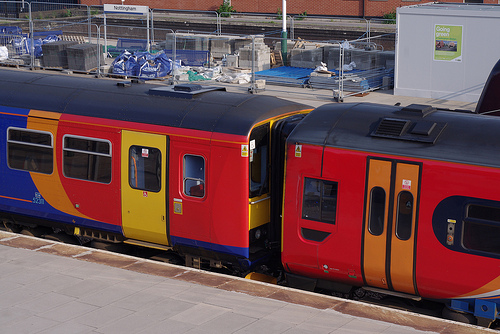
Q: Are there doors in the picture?
A: Yes, there is a door.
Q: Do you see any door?
A: Yes, there is a door.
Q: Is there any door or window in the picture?
A: Yes, there is a door.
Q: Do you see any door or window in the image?
A: Yes, there is a door.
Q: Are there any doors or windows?
A: Yes, there is a door.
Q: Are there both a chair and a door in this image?
A: No, there is a door but no chairs.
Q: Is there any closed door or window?
A: Yes, there is a closed door.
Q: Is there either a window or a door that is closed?
A: Yes, the door is closed.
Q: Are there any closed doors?
A: Yes, there is a closed door.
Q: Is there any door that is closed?
A: Yes, there is a door that is closed.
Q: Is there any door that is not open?
A: Yes, there is an closed door.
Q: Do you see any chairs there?
A: No, there are no chairs.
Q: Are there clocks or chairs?
A: No, there are no chairs or clocks.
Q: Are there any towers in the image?
A: No, there are no towers.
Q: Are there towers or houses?
A: No, there are no towers or houses.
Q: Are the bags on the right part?
A: No, the bags are on the left of the image.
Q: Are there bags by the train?
A: Yes, there are bags by the train.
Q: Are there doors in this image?
A: Yes, there is a door.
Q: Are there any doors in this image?
A: Yes, there is a door.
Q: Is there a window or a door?
A: Yes, there is a door.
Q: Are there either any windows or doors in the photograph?
A: Yes, there is a door.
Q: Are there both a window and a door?
A: Yes, there are both a door and a window.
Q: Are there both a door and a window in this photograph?
A: Yes, there are both a door and a window.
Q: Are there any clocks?
A: No, there are no clocks.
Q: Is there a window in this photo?
A: Yes, there is a window.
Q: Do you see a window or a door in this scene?
A: Yes, there is a window.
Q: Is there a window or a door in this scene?
A: Yes, there is a window.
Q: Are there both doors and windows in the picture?
A: Yes, there are both a window and doors.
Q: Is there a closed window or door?
A: Yes, there is a closed window.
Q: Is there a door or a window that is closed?
A: Yes, the window is closed.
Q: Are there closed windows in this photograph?
A: Yes, there is a closed window.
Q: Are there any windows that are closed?
A: Yes, there is a window that is closed.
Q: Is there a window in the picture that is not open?
A: Yes, there is an closed window.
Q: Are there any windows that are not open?
A: Yes, there is an closed window.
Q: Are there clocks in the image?
A: No, there are no clocks.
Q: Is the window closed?
A: Yes, the window is closed.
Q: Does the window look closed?
A: Yes, the window is closed.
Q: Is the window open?
A: No, the window is closed.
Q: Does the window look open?
A: No, the window is closed.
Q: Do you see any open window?
A: No, there is a window but it is closed.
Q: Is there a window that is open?
A: No, there is a window but it is closed.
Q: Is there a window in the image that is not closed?
A: No, there is a window but it is closed.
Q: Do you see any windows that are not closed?
A: No, there is a window but it is closed.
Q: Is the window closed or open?
A: The window is closed.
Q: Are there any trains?
A: Yes, there is a train.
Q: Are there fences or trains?
A: Yes, there is a train.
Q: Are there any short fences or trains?
A: Yes, there is a short train.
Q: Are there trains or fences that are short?
A: Yes, the train is short.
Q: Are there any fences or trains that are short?
A: Yes, the train is short.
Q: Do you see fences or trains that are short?
A: Yes, the train is short.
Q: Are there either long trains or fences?
A: Yes, there is a long train.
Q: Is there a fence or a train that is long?
A: Yes, the train is long.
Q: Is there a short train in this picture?
A: Yes, there is a short train.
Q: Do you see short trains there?
A: Yes, there is a short train.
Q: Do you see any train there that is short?
A: Yes, there is a train that is short.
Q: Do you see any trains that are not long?
A: Yes, there is a short train.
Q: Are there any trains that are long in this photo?
A: Yes, there is a long train.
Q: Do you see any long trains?
A: Yes, there is a long train.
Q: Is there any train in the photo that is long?
A: Yes, there is a train that is long.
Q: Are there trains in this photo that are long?
A: Yes, there is a train that is long.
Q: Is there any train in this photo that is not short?
A: Yes, there is a long train.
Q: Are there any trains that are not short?
A: Yes, there is a long train.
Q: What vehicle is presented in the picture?
A: The vehicle is a train.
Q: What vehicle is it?
A: The vehicle is a train.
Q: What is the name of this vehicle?
A: That is a train.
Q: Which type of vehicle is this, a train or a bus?
A: That is a train.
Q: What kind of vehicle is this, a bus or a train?
A: That is a train.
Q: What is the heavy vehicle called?
A: The vehicle is a train.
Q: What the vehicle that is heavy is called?
A: The vehicle is a train.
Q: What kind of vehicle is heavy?
A: The vehicle is a train.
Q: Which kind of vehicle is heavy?
A: The vehicle is a train.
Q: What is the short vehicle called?
A: The vehicle is a train.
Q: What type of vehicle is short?
A: The vehicle is a train.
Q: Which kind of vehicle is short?
A: The vehicle is a train.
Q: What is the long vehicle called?
A: The vehicle is a train.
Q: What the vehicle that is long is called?
A: The vehicle is a train.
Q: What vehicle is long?
A: The vehicle is a train.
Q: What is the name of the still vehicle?
A: The vehicle is a train.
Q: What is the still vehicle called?
A: The vehicle is a train.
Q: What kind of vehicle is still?
A: The vehicle is a train.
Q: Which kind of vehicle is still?
A: The vehicle is a train.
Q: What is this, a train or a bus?
A: This is a train.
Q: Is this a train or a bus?
A: This is a train.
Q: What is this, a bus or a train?
A: This is a train.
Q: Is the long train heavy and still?
A: Yes, the train is heavy and still.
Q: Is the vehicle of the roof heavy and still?
A: Yes, the train is heavy and still.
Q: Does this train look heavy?
A: Yes, the train is heavy.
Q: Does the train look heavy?
A: Yes, the train is heavy.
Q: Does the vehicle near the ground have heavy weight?
A: Yes, the train is heavy.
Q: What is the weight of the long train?
A: The train is heavy.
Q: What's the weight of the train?
A: The train is heavy.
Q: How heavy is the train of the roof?
A: The train is heavy.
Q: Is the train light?
A: No, the train is heavy.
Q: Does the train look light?
A: No, the train is heavy.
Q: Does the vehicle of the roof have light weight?
A: No, the train is heavy.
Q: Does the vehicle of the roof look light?
A: No, the train is heavy.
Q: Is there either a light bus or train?
A: No, there is a train but it is heavy.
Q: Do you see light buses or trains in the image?
A: No, there is a train but it is heavy.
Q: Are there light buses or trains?
A: No, there is a train but it is heavy.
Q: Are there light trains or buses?
A: No, there is a train but it is heavy.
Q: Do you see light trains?
A: No, there is a train but it is heavy.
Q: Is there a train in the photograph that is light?
A: No, there is a train but it is heavy.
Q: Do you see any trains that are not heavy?
A: No, there is a train but it is heavy.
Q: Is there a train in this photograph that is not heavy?
A: No, there is a train but it is heavy.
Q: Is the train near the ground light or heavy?
A: The train is heavy.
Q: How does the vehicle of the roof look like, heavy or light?
A: The train is heavy.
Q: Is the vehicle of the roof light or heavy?
A: The train is heavy.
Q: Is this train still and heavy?
A: Yes, the train is still and heavy.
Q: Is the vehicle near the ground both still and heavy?
A: Yes, the train is still and heavy.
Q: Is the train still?
A: Yes, the train is still.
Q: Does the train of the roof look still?
A: Yes, the train is still.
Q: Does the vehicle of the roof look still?
A: Yes, the train is still.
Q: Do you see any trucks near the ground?
A: No, there is a train near the ground.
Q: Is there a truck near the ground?
A: No, there is a train near the ground.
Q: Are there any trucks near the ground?
A: No, there is a train near the ground.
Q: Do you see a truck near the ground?
A: No, there is a train near the ground.